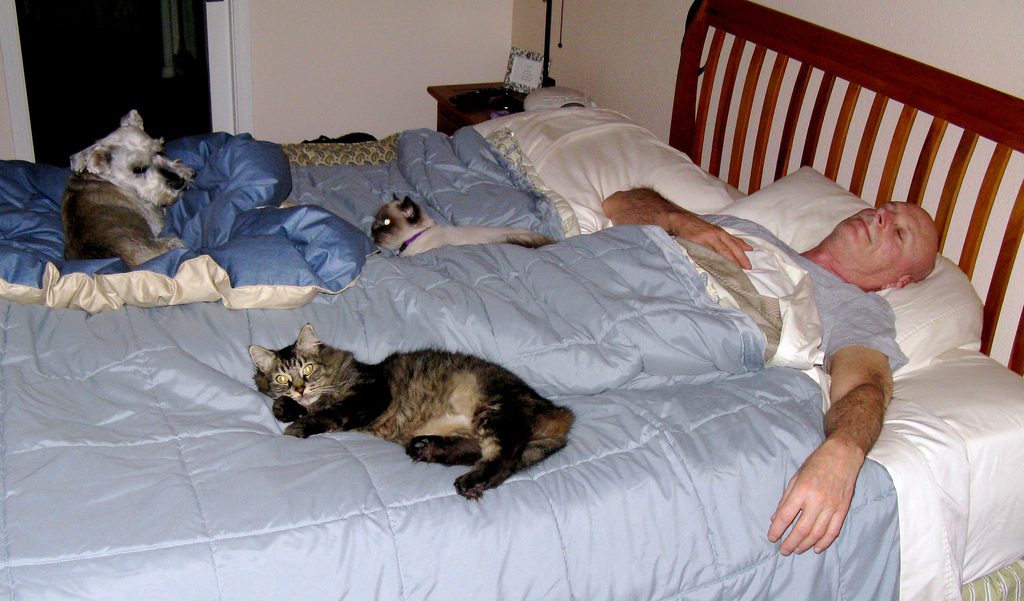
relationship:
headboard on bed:
[665, 1, 1021, 381] [0, 97, 1021, 597]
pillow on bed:
[465, 100, 745, 240] [0, 97, 1021, 597]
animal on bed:
[366, 188, 556, 261] [6, 3, 1018, 598]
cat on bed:
[237, 319, 582, 499] [306, 76, 870, 593]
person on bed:
[0, 186, 939, 557] [6, 3, 1018, 598]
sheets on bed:
[5, 128, 824, 594] [6, 3, 1018, 598]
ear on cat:
[240, 342, 280, 372] [237, 319, 582, 499]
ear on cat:
[298, 327, 321, 360] [237, 319, 582, 499]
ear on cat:
[241, 342, 278, 372] [253, 340, 587, 499]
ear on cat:
[385, 187, 409, 211] [358, 189, 563, 261]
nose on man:
[870, 196, 891, 225] [586, 166, 969, 558]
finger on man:
[761, 472, 852, 560] [586, 166, 969, 558]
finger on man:
[778, 496, 817, 560] [610, 124, 952, 559]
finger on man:
[720, 229, 752, 261] [594, 180, 939, 576]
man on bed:
[586, 166, 969, 558] [6, 3, 1018, 598]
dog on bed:
[71, 117, 215, 267] [6, 3, 1018, 598]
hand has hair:
[754, 276, 909, 596] [836, 389, 870, 439]